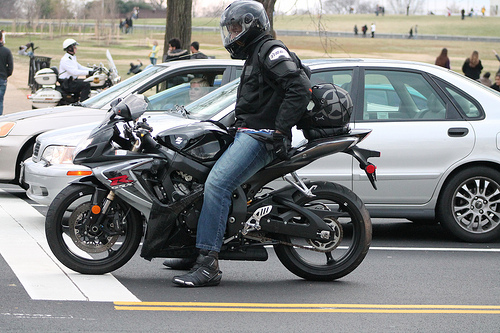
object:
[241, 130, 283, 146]
glove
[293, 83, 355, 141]
helmet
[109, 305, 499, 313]
yellow lines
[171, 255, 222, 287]
shoe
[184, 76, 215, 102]
woman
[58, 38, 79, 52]
helmet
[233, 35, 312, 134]
black jacket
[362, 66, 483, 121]
back window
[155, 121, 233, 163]
gas tank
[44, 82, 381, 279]
bike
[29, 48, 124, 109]
bike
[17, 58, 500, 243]
car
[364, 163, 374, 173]
red light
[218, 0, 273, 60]
helmet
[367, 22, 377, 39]
people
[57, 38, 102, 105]
policeman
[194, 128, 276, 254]
blue jean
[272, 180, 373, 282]
tire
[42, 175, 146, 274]
tire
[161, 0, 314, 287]
man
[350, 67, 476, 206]
door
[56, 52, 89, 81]
shirt.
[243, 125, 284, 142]
hand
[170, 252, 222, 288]
foot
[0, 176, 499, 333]
street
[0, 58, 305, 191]
vehicle